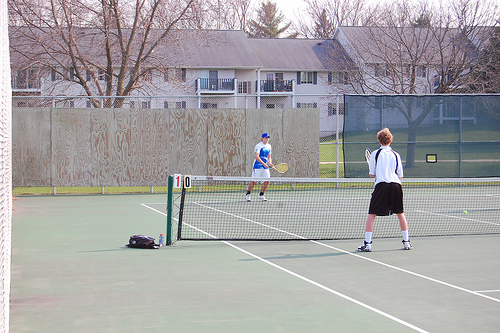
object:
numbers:
[173, 174, 191, 188]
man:
[357, 127, 412, 252]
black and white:
[368, 146, 404, 216]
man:
[246, 133, 275, 202]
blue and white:
[250, 141, 272, 184]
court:
[11, 185, 500, 333]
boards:
[12, 106, 320, 187]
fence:
[13, 94, 499, 197]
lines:
[141, 192, 500, 332]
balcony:
[194, 77, 237, 95]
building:
[7, 26, 499, 142]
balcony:
[254, 80, 295, 97]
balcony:
[11, 76, 44, 92]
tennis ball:
[463, 211, 468, 215]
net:
[176, 180, 500, 242]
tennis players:
[244, 127, 411, 252]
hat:
[261, 132, 270, 138]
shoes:
[358, 240, 414, 252]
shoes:
[245, 194, 268, 202]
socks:
[365, 230, 409, 243]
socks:
[246, 191, 264, 196]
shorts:
[368, 182, 404, 217]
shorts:
[252, 169, 271, 184]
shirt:
[368, 146, 403, 186]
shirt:
[252, 142, 271, 171]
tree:
[8, 0, 224, 108]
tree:
[293, 0, 499, 170]